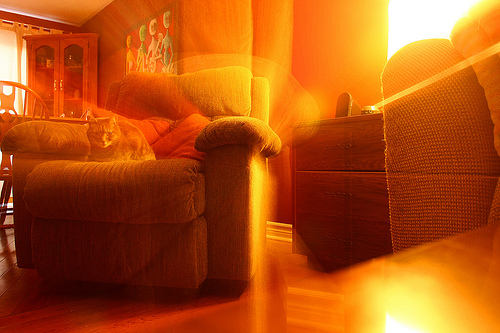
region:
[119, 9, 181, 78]
Pictures on the wall.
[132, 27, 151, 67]
Green alien in picture.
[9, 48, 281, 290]
Gray chair in the forefront.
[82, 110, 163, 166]
Cat laying in chair.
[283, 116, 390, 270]
Wooden table beside wall.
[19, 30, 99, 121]
China cabinet in corner.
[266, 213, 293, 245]
White baseboard on the wall.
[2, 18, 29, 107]
White drapes on the window.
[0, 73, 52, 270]
Wooden chair in the background.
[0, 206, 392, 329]
Brown wooden floor in the room.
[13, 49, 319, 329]
Chair on the ground.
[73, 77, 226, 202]
Cat in the chair.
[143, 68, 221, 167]
pillow on the chair.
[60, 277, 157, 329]
Wood floor under the chair.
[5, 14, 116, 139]
Cabinet against the wall.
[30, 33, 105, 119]
Glass panes on the cabinet.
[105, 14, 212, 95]
Picture on the wall.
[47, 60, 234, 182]
Cat lying on the chair.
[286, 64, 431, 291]
Cabinet on the wall.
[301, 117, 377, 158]
Drawer on the cabinet.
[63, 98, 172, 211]
cat on the chair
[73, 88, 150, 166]
cat on the chair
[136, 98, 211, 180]
pillows on the chair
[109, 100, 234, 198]
pillows on the chair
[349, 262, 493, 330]
reflection of light on the floor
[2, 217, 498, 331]
wooden floor of the room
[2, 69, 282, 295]
a stuffed easy chair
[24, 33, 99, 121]
a cabinet in the corner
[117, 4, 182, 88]
framed art on the wall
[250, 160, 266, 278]
reflection on side of chair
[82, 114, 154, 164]
cat sitting on a chair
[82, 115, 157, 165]
cat laying on a chair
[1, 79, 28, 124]
back of a wooden chair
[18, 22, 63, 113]
curtain hanging in the back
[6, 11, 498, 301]
a blurry scene of a chair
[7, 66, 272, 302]
a chair with a cat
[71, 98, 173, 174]
a cat in a chair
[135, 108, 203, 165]
orange pillows in the chair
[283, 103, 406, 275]
a brown cabinet on a wood floor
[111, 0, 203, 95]
a picture behind the chair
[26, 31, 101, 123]
a brown corner cabinet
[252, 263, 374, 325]
a hard wood floor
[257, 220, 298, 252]
a white base board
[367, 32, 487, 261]
a checker arm of a chair